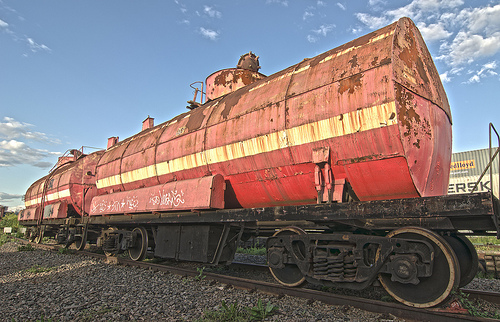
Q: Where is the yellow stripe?
A: On the tank car.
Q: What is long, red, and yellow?
A: The tanker cars.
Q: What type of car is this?
A: A cargo car.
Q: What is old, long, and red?
A: Two tanker cars.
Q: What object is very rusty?
A: The tanker cars.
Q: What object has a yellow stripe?
A: The tanker car.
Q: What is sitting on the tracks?
A: A train.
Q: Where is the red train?
A: On train tracks.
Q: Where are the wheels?
A: Beneath the train.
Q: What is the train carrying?
A: Materials.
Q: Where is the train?
A: On the tracks.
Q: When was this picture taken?
A: Daytime.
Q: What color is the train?
A: Red.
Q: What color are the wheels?
A: Black.